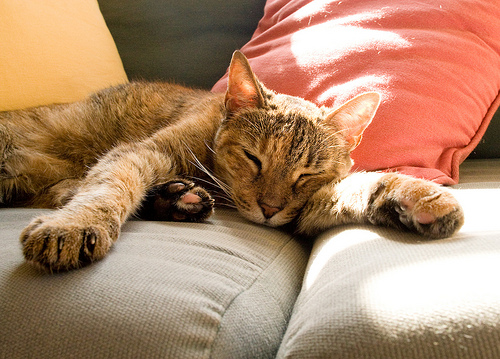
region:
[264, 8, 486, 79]
this is a pillow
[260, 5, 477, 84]
the pillow is small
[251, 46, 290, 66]
the pillow is red in color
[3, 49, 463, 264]
this is a cat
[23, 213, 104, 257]
this is a paw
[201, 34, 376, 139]
these are the ears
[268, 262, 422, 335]
this is a cushion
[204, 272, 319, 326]
the cushion is grey in color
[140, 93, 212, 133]
the fur is brown in color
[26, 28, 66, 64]
the area is yellow in color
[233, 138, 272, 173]
right eye on cat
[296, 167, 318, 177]
left eye on cat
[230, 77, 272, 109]
right ear on cat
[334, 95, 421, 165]
left ear on cat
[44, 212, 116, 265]
right front paw on cat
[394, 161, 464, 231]
left front paw on cat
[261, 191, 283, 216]
small nose on cat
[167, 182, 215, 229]
back paw on cat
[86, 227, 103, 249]
small claw on cat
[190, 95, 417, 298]
cat laying on couch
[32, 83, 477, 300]
the cat is slepping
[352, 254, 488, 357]
light is on the soffa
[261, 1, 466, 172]
the pillow is orange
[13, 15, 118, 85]
the pillow is yellow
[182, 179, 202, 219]
the toes are pink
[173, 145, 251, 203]
the whiskers are white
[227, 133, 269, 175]
one eye is open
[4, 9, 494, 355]
the scene is indoors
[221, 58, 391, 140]
the cat ears are two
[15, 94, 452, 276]
the cat is relaxed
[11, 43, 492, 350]
a brown cat on a couch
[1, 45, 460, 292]
the brown cat has black stripes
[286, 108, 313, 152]
black stripes of cat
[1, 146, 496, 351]
brown cushions of a couch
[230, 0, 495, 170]
a pink cushion behind a cat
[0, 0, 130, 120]
a yellow cushion behind a cat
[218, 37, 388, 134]
pointy ears of cat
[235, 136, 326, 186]
eyes of cat are closed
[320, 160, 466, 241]
a leg on right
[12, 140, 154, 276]
a leg on left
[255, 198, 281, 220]
The cats nose is pink.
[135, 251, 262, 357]
The couch is grey.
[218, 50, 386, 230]
The cats face is brown and black.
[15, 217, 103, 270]
The cats nails are long.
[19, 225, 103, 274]
The cats nails are sharp.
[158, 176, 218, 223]
The cats paw pads are pink.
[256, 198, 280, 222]
The cats nose is small.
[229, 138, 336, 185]
The cats eyes are closed.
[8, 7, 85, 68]
The pillow is yellow.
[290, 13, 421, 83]
The pillow is peach in color.